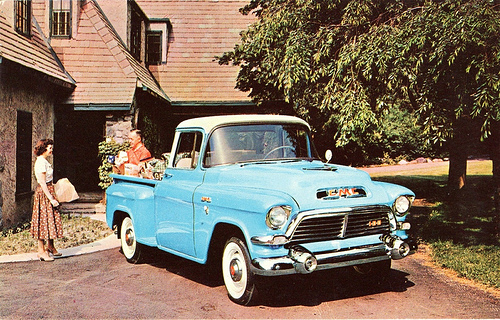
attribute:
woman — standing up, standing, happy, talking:
[31, 138, 65, 262]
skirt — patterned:
[31, 182, 64, 239]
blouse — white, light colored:
[34, 155, 53, 182]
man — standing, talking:
[113, 129, 153, 176]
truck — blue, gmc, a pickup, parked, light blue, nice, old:
[107, 114, 417, 307]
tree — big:
[211, 1, 500, 199]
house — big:
[1, 0, 293, 232]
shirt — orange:
[126, 144, 152, 165]